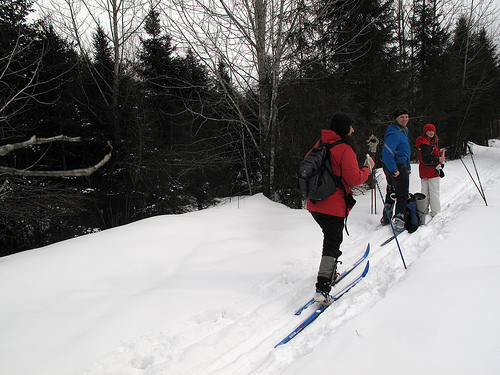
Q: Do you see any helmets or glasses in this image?
A: No, there are no glasses or helmets.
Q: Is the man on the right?
A: Yes, the man is on the right of the image.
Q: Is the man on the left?
A: No, the man is on the right of the image.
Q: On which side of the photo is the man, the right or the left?
A: The man is on the right of the image.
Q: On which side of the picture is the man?
A: The man is on the right of the image.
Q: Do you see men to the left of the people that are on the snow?
A: Yes, there is a man to the left of the people.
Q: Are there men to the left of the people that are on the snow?
A: Yes, there is a man to the left of the people.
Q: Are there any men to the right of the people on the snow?
A: No, the man is to the left of the people.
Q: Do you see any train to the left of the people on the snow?
A: No, there is a man to the left of the people.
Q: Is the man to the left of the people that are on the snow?
A: Yes, the man is to the left of the people.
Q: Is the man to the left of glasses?
A: No, the man is to the left of the people.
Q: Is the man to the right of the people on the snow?
A: No, the man is to the left of the people.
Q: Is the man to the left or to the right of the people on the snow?
A: The man is to the left of the people.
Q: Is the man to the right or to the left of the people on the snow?
A: The man is to the left of the people.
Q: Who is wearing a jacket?
A: The man is wearing a jacket.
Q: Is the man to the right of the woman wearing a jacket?
A: Yes, the man is wearing a jacket.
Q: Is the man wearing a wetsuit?
A: No, the man is wearing a jacket.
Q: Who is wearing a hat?
A: The man is wearing a hat.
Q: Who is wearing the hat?
A: The man is wearing a hat.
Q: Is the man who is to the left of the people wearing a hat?
A: Yes, the man is wearing a hat.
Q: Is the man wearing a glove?
A: No, the man is wearing a hat.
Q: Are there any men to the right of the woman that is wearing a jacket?
A: Yes, there is a man to the right of the woman.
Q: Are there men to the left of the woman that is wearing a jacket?
A: No, the man is to the right of the woman.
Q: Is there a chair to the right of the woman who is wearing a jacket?
A: No, there is a man to the right of the woman.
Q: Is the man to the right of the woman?
A: Yes, the man is to the right of the woman.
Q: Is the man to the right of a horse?
A: No, the man is to the right of the woman.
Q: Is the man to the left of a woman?
A: No, the man is to the right of a woman.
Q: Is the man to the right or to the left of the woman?
A: The man is to the right of the woman.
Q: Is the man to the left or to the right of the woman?
A: The man is to the right of the woman.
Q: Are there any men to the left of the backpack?
A: No, the man is to the right of the backpack.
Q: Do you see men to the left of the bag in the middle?
A: No, the man is to the right of the backpack.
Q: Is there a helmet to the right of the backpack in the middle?
A: No, there is a man to the right of the backpack.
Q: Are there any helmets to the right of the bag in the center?
A: No, there is a man to the right of the backpack.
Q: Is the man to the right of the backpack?
A: Yes, the man is to the right of the backpack.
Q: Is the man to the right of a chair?
A: No, the man is to the right of the backpack.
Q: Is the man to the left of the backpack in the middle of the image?
A: No, the man is to the right of the backpack.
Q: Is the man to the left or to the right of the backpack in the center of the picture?
A: The man is to the right of the backpack.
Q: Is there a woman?
A: Yes, there is a woman.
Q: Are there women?
A: Yes, there is a woman.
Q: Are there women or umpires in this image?
A: Yes, there is a woman.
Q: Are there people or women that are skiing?
A: Yes, the woman is skiing.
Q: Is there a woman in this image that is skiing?
A: Yes, there is a woman that is skiing.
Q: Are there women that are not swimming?
A: Yes, there is a woman that is skiing.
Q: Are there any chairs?
A: No, there are no chairs.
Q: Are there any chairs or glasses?
A: No, there are no chairs or glasses.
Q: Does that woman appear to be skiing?
A: Yes, the woman is skiing.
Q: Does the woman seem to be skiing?
A: Yes, the woman is skiing.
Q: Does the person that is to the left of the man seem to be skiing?
A: Yes, the woman is skiing.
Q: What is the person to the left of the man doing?
A: The woman is skiing.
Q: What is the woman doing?
A: The woman is skiing.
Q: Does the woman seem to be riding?
A: No, the woman is skiing.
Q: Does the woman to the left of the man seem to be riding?
A: No, the woman is skiing.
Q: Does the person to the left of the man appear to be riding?
A: No, the woman is skiing.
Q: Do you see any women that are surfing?
A: No, there is a woman but she is skiing.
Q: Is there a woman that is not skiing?
A: No, there is a woman but she is skiing.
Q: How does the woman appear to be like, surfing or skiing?
A: The woman is skiing.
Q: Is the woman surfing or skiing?
A: The woman is skiing.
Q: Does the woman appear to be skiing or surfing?
A: The woman is skiing.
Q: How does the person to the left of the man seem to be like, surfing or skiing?
A: The woman is skiing.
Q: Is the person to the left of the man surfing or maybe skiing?
A: The woman is skiing.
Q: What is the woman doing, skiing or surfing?
A: The woman is skiing.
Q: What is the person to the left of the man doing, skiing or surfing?
A: The woman is skiing.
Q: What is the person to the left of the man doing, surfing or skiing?
A: The woman is skiing.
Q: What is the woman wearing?
A: The woman is wearing a jacket.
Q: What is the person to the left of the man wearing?
A: The woman is wearing a jacket.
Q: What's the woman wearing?
A: The woman is wearing a jacket.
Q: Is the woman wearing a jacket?
A: Yes, the woman is wearing a jacket.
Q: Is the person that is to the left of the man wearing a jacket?
A: Yes, the woman is wearing a jacket.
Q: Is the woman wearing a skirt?
A: No, the woman is wearing a jacket.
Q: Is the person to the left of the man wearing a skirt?
A: No, the woman is wearing a jacket.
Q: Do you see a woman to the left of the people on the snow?
A: Yes, there is a woman to the left of the people.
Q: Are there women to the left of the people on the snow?
A: Yes, there is a woman to the left of the people.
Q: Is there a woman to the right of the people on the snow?
A: No, the woman is to the left of the people.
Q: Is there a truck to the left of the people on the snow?
A: No, there is a woman to the left of the people.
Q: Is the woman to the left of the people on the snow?
A: Yes, the woman is to the left of the people.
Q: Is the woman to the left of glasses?
A: No, the woman is to the left of the people.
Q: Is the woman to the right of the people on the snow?
A: No, the woman is to the left of the people.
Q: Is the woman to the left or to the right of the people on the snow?
A: The woman is to the left of the people.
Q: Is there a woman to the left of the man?
A: Yes, there is a woman to the left of the man.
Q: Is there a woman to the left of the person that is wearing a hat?
A: Yes, there is a woman to the left of the man.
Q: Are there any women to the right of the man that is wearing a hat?
A: No, the woman is to the left of the man.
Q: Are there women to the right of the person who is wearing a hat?
A: No, the woman is to the left of the man.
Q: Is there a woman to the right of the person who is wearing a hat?
A: No, the woman is to the left of the man.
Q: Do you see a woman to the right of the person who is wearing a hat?
A: No, the woman is to the left of the man.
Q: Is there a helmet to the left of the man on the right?
A: No, there is a woman to the left of the man.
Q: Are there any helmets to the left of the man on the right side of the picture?
A: No, there is a woman to the left of the man.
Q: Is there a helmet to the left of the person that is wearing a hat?
A: No, there is a woman to the left of the man.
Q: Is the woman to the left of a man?
A: Yes, the woman is to the left of a man.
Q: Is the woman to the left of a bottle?
A: No, the woman is to the left of a man.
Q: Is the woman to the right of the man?
A: No, the woman is to the left of the man.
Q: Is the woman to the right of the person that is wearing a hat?
A: No, the woman is to the left of the man.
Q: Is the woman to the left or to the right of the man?
A: The woman is to the left of the man.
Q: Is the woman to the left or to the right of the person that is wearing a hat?
A: The woman is to the left of the man.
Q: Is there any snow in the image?
A: Yes, there is snow.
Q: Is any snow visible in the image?
A: Yes, there is snow.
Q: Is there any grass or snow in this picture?
A: Yes, there is snow.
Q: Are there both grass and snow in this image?
A: No, there is snow but no grass.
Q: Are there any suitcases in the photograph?
A: No, there are no suitcases.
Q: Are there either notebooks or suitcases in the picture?
A: No, there are no suitcases or notebooks.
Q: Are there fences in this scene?
A: No, there are no fences.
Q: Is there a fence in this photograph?
A: No, there are no fences.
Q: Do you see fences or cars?
A: No, there are no fences or cars.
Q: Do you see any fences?
A: No, there are no fences.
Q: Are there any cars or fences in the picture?
A: No, there are no fences or cars.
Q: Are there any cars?
A: No, there are no cars.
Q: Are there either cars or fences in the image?
A: No, there are no cars or fences.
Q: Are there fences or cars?
A: No, there are no cars or fences.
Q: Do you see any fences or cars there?
A: No, there are no cars or fences.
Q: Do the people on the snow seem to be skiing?
A: Yes, the people are skiing.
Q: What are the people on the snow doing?
A: The people are skiing.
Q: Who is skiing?
A: The people are skiing.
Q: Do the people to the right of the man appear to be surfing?
A: No, the people are skiing.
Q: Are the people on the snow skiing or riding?
A: The people are skiing.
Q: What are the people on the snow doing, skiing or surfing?
A: The people are skiing.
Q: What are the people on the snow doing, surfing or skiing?
A: The people are skiing.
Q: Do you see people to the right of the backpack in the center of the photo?
A: Yes, there are people to the right of the backpack.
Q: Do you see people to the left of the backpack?
A: No, the people are to the right of the backpack.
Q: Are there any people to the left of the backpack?
A: No, the people are to the right of the backpack.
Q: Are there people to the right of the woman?
A: Yes, there are people to the right of the woman.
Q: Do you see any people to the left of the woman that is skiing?
A: No, the people are to the right of the woman.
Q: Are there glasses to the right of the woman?
A: No, there are people to the right of the woman.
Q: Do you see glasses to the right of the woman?
A: No, there are people to the right of the woman.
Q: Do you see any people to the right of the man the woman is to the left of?
A: Yes, there are people to the right of the man.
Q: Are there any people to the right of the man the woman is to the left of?
A: Yes, there are people to the right of the man.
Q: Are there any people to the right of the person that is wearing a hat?
A: Yes, there are people to the right of the man.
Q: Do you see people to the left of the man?
A: No, the people are to the right of the man.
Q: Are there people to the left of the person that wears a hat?
A: No, the people are to the right of the man.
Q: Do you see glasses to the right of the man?
A: No, there are people to the right of the man.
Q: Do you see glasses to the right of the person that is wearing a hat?
A: No, there are people to the right of the man.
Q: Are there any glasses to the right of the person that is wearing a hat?
A: No, there are people to the right of the man.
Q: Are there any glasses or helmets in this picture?
A: No, there are no glasses or helmets.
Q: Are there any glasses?
A: No, there are no glasses.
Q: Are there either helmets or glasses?
A: No, there are no glasses or helmets.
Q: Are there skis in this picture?
A: Yes, there are skis.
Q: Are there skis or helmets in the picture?
A: Yes, there are skis.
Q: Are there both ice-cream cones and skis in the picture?
A: No, there are skis but no ice-cream cones.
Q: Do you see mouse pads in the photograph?
A: No, there are no mouse pads.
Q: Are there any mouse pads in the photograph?
A: No, there are no mouse pads.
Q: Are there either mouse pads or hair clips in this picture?
A: No, there are no mouse pads or hair clips.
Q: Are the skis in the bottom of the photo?
A: Yes, the skis are in the bottom of the image.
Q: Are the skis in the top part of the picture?
A: No, the skis are in the bottom of the image.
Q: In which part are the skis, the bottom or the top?
A: The skis are in the bottom of the image.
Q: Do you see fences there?
A: No, there are no fences.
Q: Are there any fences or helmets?
A: No, there are no fences or helmets.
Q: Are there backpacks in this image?
A: Yes, there is a backpack.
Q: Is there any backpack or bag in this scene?
A: Yes, there is a backpack.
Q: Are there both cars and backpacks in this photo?
A: No, there is a backpack but no cars.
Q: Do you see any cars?
A: No, there are no cars.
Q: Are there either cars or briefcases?
A: No, there are no cars or briefcases.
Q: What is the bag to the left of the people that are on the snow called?
A: The bag is a backpack.